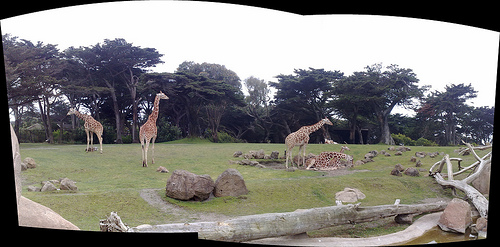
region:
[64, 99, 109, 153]
giraffe in a field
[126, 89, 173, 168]
giraffe in a field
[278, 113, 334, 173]
giraffe in a field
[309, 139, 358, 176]
giraffe in a field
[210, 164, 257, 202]
rock in a field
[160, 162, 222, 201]
rock in a field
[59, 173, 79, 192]
rock in a field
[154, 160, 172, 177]
rock in a field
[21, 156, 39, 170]
rock in a field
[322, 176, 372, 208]
rock in a field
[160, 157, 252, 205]
two grey rock on green field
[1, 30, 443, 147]
green trees bordering green field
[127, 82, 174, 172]
brown and tan giraffe in green field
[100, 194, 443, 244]
long wooden log lying across a green grass field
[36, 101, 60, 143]
brown tree trunk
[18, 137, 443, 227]
large green grass field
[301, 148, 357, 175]
one giraffe lying down on ground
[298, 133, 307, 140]
brown and white spotted pattern on fur of giraffe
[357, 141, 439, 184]
array of rocks in green field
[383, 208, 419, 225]
hole in side of grey log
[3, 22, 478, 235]
giraffes in a green field with rocks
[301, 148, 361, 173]
giraffe laying in a green field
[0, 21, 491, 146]
green trees with bright white sky above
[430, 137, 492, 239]
gray dead tree laying on the ground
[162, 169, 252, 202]
two large brown rocks laying on the green grass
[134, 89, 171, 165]
brown and tan giraffe walking in a green field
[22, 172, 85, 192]
cluster of small rocks on green field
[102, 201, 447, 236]
gray dead tree laying on the green field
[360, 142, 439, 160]
small rocks laying on the green grass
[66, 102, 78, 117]
head of a giraffe standing in a green field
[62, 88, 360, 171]
giraffe in park walking on grass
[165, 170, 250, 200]
two large rocks in park with giraffe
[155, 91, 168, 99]
head of one giraffe in park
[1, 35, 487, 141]
very large trees in park in the background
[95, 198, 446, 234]
large tree trunk lying down in front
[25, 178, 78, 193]
rocks in park grass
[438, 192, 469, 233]
bolder under tree in front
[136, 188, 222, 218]
stream of water in giraffe park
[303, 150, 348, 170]
one giraffe laying down on ground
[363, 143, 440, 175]
a lot of ricks in the ground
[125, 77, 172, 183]
Giraffe in a field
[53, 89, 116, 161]
Giraffe in a field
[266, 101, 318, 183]
Giraffe in a field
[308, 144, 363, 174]
Giraffe in a field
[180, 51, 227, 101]
Green tree in the field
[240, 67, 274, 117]
Green tree in the field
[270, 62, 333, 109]
Green tree in the field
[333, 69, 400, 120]
Green tree in the field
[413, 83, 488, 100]
Green tree in the field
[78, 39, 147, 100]
Green tree in the field